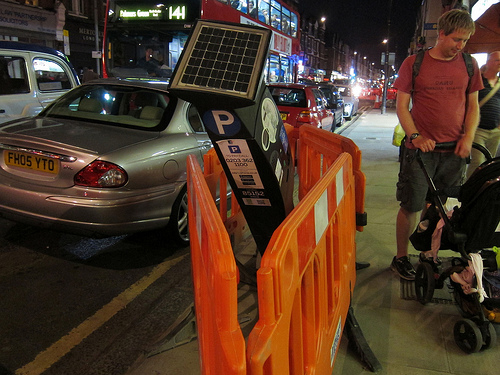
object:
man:
[390, 5, 484, 280]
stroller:
[414, 141, 500, 354]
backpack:
[411, 47, 474, 92]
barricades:
[186, 122, 368, 374]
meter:
[165, 18, 295, 256]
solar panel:
[166, 19, 272, 103]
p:
[210, 111, 234, 135]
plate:
[3, 147, 60, 172]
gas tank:
[163, 159, 179, 180]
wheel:
[413, 262, 436, 306]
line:
[8, 246, 190, 375]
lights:
[351, 84, 367, 98]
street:
[1, 77, 359, 371]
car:
[0, 75, 232, 247]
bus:
[104, 0, 304, 108]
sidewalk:
[325, 97, 499, 370]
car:
[260, 82, 336, 132]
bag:
[392, 122, 406, 147]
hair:
[436, 10, 475, 38]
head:
[437, 8, 475, 59]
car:
[0, 40, 83, 125]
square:
[313, 188, 328, 244]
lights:
[74, 160, 127, 188]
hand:
[412, 135, 436, 153]